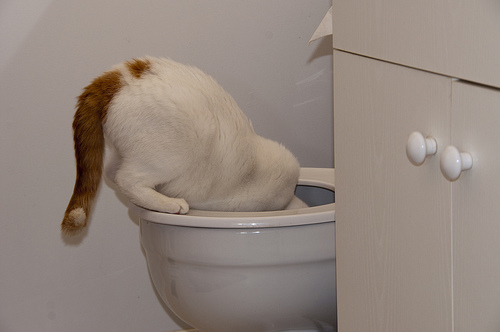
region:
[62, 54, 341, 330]
A cat drinking out of a toilet.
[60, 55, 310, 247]
Brown and white cat.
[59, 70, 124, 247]
Brown tail of a cat.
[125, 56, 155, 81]
Brown patch of fur on the cat's back.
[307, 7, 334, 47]
Edge of white toilet paper.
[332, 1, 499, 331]
White bathroom cabinet.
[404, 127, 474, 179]
White nobs on the cabinet doors.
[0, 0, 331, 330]
White bathroom wall.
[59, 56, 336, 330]
Cat with its head in the toilet.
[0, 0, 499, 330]
A white bathroom with a cat leaning into a toilet.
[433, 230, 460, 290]
part f a line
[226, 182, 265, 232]
edge of a lid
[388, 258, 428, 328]
part of a wal;l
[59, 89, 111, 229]
the tail is brown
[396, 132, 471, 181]
the knob are white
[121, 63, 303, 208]
the fur is white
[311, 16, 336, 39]
the tissue is white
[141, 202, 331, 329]
the toilet is white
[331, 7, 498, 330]
the shelf is white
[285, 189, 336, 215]
the cat's head is in the toilet bowl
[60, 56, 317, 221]
the cat is in the toilet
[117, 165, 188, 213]
the leg is on the top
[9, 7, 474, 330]
the photo is indoor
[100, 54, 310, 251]
cat is in toilet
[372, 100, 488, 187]
white handles on doors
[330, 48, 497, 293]
white doors near toilet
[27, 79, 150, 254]
cat has brown tail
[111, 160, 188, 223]
cat has white paws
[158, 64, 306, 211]
cat has white back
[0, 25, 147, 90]
white wall behind cat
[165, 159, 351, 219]
toilet has white seat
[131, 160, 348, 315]
toilet has white bowl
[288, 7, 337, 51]
toilet paper is white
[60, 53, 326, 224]
the cat is on the toilet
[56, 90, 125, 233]
the tail is brown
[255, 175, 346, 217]
head is in the toilet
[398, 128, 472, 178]
the knobs are white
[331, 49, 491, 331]
the cabinets are closed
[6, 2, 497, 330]
the scene is in the toilet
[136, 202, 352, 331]
the toilet is white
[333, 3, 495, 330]
the cabinetsare wooden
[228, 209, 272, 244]
light reflection is on the toilet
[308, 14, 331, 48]
th paper is brown